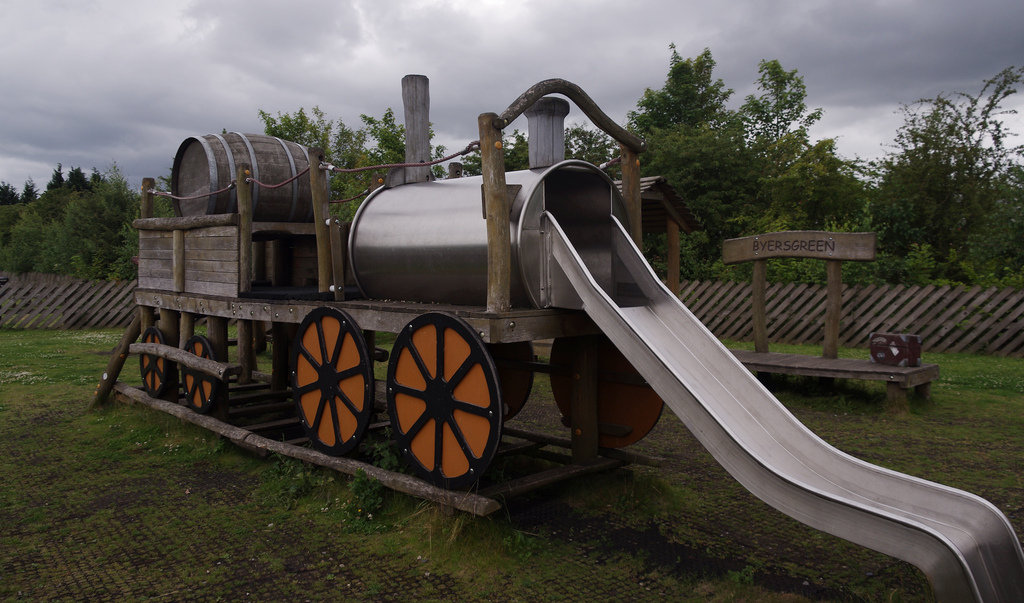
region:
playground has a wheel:
[288, 307, 369, 453]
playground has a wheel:
[393, 318, 495, 483]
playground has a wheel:
[177, 340, 225, 410]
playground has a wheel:
[550, 340, 659, 449]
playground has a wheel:
[491, 347, 531, 427]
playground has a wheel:
[262, 319, 302, 373]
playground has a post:
[303, 158, 335, 292]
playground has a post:
[474, 115, 510, 311]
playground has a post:
[620, 144, 637, 242]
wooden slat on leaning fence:
[908, 283, 970, 340]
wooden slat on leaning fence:
[882, 277, 949, 336]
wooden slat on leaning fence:
[830, 273, 907, 344]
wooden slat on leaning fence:
[756, 277, 824, 336]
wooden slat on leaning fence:
[757, 273, 808, 316]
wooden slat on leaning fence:
[699, 269, 747, 327]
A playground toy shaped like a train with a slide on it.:
[100, 62, 1014, 600]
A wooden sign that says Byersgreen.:
[717, 203, 895, 287]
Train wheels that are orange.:
[125, 297, 533, 509]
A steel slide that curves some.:
[530, 151, 1022, 601]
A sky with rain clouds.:
[8, 6, 1023, 165]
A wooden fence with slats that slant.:
[5, 253, 1020, 358]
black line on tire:
[447, 394, 485, 421]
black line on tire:
[446, 353, 473, 388]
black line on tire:
[434, 320, 448, 390]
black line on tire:
[405, 340, 434, 382]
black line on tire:
[392, 377, 431, 406]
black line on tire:
[399, 412, 428, 448]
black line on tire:
[428, 415, 448, 480]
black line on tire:
[443, 410, 476, 464]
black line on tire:
[335, 387, 362, 416]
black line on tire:
[325, 390, 346, 449]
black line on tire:
[447, 349, 483, 397]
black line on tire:
[447, 394, 492, 423]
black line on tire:
[443, 410, 473, 471]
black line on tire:
[401, 403, 430, 445]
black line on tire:
[389, 371, 418, 403]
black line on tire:
[404, 333, 427, 376]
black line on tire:
[327, 394, 347, 445]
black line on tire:
[332, 385, 361, 421]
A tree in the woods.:
[869, 106, 956, 290]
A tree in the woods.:
[922, 62, 1006, 354]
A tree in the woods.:
[43, 169, 129, 267]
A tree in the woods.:
[266, 106, 331, 173]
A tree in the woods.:
[329, 115, 399, 191]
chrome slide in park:
[543, 208, 1021, 600]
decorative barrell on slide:
[169, 130, 321, 223]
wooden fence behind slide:
[2, 270, 1021, 360]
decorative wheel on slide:
[549, 333, 664, 451]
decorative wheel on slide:
[483, 337, 530, 423]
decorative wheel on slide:
[386, 312, 501, 492]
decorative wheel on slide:
[290, 306, 371, 456]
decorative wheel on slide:
[179, 337, 222, 415]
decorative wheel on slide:
[139, 330, 175, 399]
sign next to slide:
[715, 229, 876, 262]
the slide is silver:
[547, 209, 1022, 601]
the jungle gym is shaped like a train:
[87, 70, 1018, 601]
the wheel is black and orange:
[384, 310, 501, 489]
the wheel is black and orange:
[286, 303, 372, 455]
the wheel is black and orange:
[182, 334, 220, 411]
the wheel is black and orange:
[136, 328, 169, 393]